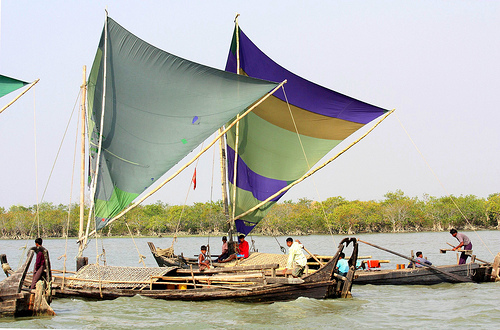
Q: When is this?
A: Daytime.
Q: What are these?
A: Boats.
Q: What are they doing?
A: Sailing.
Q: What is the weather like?
A: Sunny.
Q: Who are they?
A: Sailers.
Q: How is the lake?
A: Wavy.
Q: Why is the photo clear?
A: To be seen.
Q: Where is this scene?
A: In a river.